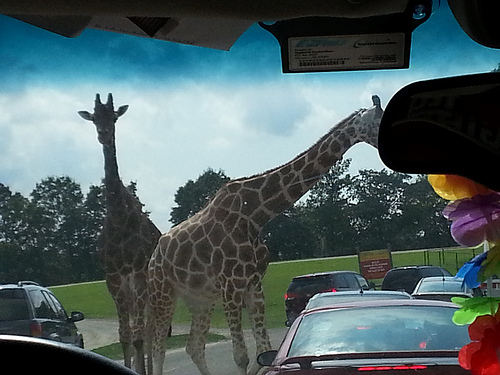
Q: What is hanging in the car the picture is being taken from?
A: Hawaiian lei.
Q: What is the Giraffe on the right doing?
A: Leaning over a car.